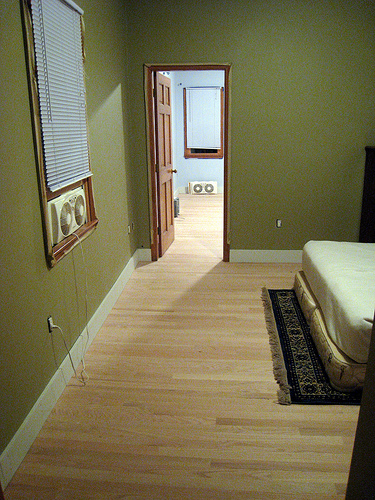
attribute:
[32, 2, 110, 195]
window shades — white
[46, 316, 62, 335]
plug — small, electrical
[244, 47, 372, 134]
wall — green, painted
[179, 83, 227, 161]
window — rectangular 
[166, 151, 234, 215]
fans — double electrical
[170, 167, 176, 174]
door knob — metal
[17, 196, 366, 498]
floor — hardwood